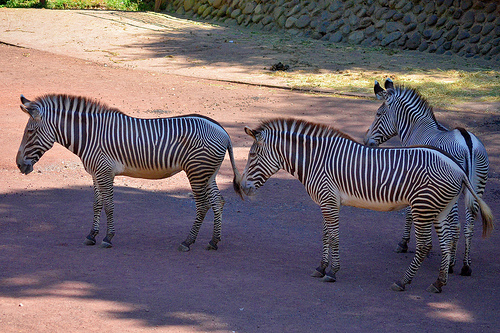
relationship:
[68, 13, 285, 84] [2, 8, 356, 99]
part of ground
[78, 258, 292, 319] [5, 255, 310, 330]
part of ground